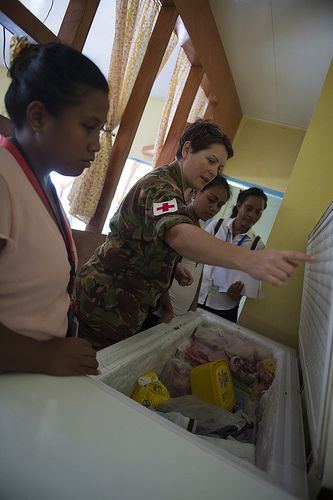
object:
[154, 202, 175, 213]
cross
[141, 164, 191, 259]
sleeve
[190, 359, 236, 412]
container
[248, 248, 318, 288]
hand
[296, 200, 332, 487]
door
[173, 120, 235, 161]
hair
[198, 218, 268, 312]
shirt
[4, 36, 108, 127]
hair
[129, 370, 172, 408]
bag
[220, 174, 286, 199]
edgeing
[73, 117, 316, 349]
woman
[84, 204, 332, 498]
freezer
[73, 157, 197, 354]
uniform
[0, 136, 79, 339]
shirt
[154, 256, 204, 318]
shirt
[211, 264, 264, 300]
papers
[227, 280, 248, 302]
hand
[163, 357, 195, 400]
meat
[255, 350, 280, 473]
frost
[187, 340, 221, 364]
meat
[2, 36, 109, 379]
woman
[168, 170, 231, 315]
woman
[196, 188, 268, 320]
woman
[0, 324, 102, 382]
arm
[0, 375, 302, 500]
freezer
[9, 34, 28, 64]
ribbon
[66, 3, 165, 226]
curtain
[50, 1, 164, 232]
window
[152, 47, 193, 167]
curtain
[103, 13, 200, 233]
window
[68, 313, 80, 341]
badge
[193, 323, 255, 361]
food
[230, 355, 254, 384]
food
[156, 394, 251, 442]
food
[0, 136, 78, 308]
ribbon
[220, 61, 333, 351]
wall